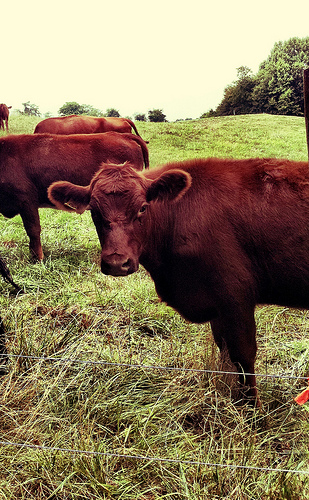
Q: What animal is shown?
A: Cow.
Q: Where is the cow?
A: In the field.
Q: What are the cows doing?
A: Eating.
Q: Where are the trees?
A: Behind the pasture.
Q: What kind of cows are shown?
A: Brown cows.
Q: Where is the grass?
A: On the ground.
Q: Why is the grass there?
A: For the cows.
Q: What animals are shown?
A: Cows.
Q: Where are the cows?
A: In a pasture.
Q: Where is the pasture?
A: In the country.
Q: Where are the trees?
A: Behind the hill.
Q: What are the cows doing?
A: Standing.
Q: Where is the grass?
A: On the ground.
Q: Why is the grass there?
A: For the cows to eat.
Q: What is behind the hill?
A: The trees.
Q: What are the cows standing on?
A: A hill.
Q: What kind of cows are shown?
A: Brown.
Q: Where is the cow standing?
A: Next to a fence.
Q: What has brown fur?
A: The cows.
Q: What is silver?
A: The barbed wire.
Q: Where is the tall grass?
A: In the front of the cow.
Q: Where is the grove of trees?
A: Behind the hill.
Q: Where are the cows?
A: In the pasture.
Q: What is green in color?
A: The grass and leaves.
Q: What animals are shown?
A: Cows.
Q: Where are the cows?
A: A field.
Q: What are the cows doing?
A: Grazing.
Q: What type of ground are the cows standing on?
A: Grass.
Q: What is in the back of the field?
A: Trees.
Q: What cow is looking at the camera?
A: The one in the foreground.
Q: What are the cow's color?
A: Brown.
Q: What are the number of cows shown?
A: 4.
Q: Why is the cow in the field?
A: Grazing.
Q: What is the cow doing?
A: Standing in the field.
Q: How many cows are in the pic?
A: 4.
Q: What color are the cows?
A: Brown.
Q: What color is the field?
A: Green.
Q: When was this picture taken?
A: During the daytime.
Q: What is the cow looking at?
A: The camera.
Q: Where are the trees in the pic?
A: Above the hill.